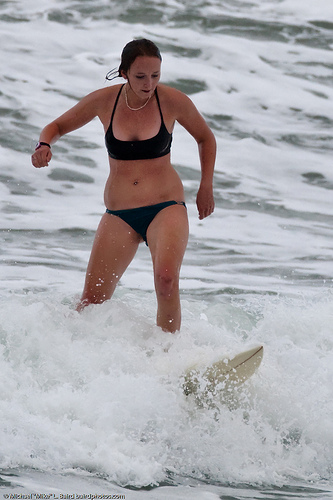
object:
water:
[1, 0, 331, 496]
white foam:
[218, 98, 330, 255]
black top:
[104, 83, 172, 161]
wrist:
[35, 140, 53, 150]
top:
[104, 83, 171, 163]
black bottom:
[104, 197, 189, 243]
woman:
[29, 34, 217, 335]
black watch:
[34, 141, 50, 150]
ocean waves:
[217, 10, 327, 147]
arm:
[37, 84, 111, 145]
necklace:
[124, 85, 154, 112]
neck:
[125, 80, 136, 98]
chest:
[116, 116, 156, 143]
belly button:
[133, 182, 137, 186]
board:
[180, 344, 263, 403]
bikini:
[105, 200, 187, 246]